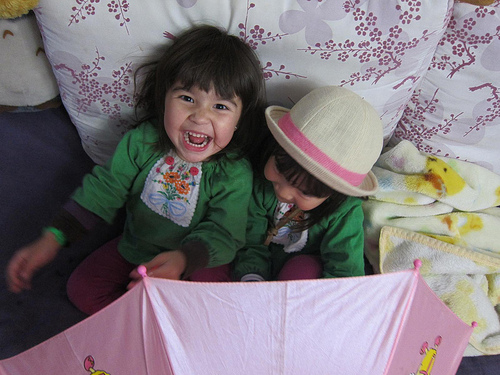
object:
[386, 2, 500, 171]
pillow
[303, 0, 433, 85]
designs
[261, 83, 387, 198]
hat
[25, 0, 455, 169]
pillow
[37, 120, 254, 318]
toddler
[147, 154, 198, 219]
flowers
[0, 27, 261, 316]
girl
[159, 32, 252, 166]
head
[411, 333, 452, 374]
design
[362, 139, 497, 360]
blanket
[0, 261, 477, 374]
pink umbrella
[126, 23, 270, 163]
hair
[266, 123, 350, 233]
hair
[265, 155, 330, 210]
face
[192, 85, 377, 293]
girl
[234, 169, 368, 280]
green shirt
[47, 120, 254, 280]
green shirt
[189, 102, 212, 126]
nose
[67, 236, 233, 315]
pants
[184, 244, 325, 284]
pants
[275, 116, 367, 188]
stripe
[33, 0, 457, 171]
blanket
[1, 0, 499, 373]
bed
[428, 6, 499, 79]
flowers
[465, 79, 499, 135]
flowers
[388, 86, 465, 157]
flowers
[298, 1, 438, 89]
flowers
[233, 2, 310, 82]
flowers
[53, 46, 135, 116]
flowers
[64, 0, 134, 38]
flowers